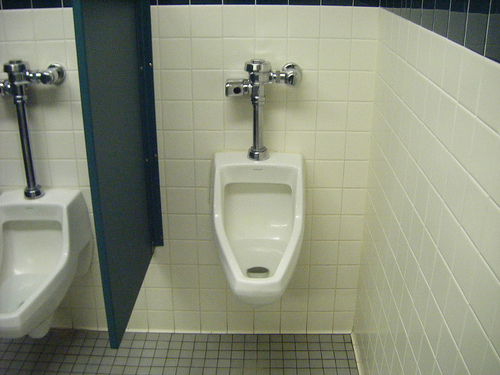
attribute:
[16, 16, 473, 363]
bathroom — mens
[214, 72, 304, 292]
urinal — higher up, higher, porcelain, white, automatic flusher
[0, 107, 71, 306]
urinal — lower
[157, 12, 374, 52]
tile — white, cream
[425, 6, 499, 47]
tile — blue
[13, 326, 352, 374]
tile — gray, small, square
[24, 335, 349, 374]
floor — tile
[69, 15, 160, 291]
divider — blue, dark blue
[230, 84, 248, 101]
sensor — automatic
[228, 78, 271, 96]
flushing apparatus — silver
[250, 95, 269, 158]
pipes — silver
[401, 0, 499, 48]
tiles — dark, black, row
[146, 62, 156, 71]
screws — silver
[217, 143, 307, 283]
toilet — hanging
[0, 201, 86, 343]
toilet — lower